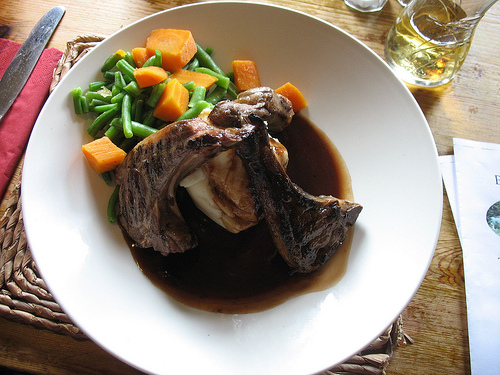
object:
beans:
[121, 94, 134, 143]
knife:
[0, 5, 67, 122]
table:
[2, 3, 499, 364]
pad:
[0, 32, 448, 374]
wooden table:
[2, 3, 498, 371]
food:
[212, 85, 364, 275]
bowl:
[19, 0, 442, 373]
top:
[17, 27, 71, 53]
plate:
[15, 0, 447, 373]